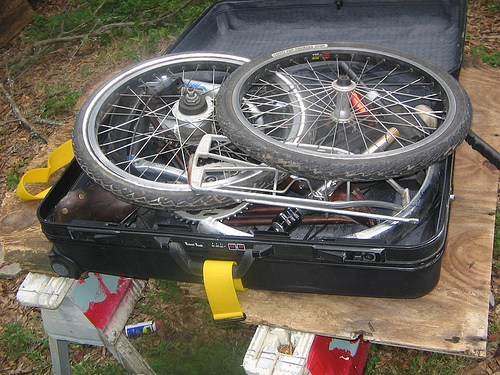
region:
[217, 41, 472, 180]
A bike tire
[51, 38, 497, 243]
A folded bike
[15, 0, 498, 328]
A bike inside of a suit case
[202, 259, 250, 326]
A yellow strap on a suitcase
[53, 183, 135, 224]
A brown bike seat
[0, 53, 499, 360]
A piece of ply wood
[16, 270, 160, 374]
A peeling saw horse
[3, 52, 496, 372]
A saw horse table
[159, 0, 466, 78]
A black and grey suitcase lid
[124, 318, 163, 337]
A can of WD40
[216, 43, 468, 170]
a bike tire sits on top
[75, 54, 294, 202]
bike tire sits below top tire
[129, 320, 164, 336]
can of engine lubricant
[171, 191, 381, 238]
bike parts in suitcase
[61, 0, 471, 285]
suitcase is left open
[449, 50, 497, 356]
slab of wood under suitcase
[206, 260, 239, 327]
suitcase has yellow strap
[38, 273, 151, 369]
blue table stand ; right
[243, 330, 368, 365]
part of table stand ; left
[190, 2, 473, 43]
lid of the suitcase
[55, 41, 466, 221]
two wheels on toolbox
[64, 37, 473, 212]
wheels are in a suit case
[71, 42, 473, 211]
the wheels have spokes and black tires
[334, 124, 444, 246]
a chrome fender is in the suitcase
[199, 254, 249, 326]
a yellow ribbon is on the handle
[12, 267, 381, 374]
wood saw horses are under the suit case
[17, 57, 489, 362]
plywood is under the suit case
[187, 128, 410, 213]
a white rear bike rack is in the case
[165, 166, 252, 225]
a chain sprocket is under the wheels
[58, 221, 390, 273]
locks are open on the suit case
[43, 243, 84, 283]
the suitcase has wheels on the bottom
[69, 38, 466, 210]
the wheels of the bike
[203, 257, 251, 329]
the strap on the handle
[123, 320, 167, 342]
the can on the ground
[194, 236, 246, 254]
the lock on the luggage bag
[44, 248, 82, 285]
the black wheel of the bag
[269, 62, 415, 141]
the rim on the tire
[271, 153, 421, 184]
the tread on the tire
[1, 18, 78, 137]
the branches on the gound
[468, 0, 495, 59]
the leaves on the ground behind the bag